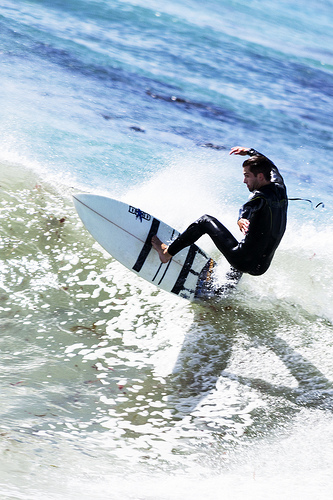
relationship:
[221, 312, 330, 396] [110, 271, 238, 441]
shadows on water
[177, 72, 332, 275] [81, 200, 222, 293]
man on surfboard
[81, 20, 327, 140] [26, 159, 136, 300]
ocean has waves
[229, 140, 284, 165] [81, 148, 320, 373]
arm of surfer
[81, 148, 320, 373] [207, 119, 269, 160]
surfer has arms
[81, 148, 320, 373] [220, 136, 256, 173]
surfer has hand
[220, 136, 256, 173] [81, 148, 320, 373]
hand of surfer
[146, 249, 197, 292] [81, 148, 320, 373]
foot of surfer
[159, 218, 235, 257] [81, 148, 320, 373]
leg of surfer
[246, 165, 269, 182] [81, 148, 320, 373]
ear of surfer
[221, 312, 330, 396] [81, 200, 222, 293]
shadows of surfboard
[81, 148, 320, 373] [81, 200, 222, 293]
surfer on surfboard